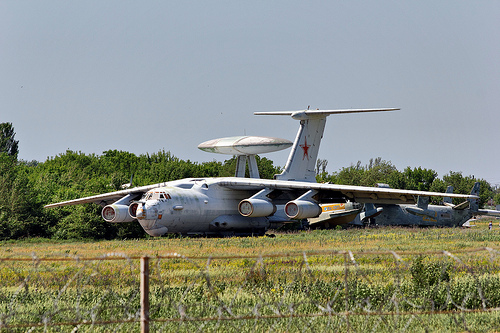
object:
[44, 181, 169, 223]
right side wing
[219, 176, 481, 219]
left side wing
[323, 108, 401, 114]
left wing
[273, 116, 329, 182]
tail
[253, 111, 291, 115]
right wing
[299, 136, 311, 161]
star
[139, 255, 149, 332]
post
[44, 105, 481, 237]
plane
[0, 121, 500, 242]
tree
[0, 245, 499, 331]
barb wire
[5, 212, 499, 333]
grass area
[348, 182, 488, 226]
plane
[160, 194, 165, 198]
window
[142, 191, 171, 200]
cockpit area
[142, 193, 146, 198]
window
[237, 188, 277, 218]
engine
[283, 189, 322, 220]
engine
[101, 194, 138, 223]
engine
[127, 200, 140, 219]
engine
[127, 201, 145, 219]
nose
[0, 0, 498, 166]
sky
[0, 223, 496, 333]
field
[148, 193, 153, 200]
window